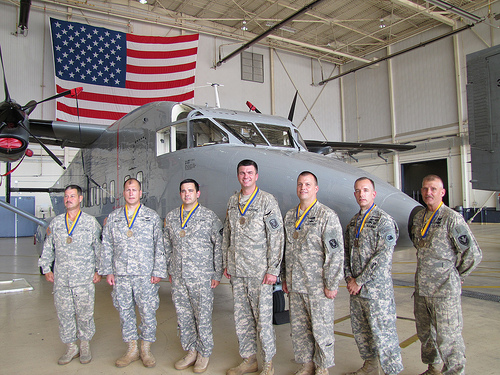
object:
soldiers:
[54, 149, 409, 304]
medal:
[168, 195, 206, 238]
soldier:
[154, 163, 220, 316]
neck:
[174, 201, 210, 218]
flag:
[59, 19, 208, 133]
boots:
[117, 332, 168, 374]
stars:
[62, 3, 114, 64]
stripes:
[115, 52, 246, 145]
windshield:
[221, 125, 297, 147]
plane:
[154, 101, 368, 206]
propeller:
[13, 114, 61, 184]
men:
[45, 158, 478, 341]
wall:
[27, 12, 281, 120]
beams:
[325, 5, 393, 58]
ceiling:
[161, 11, 463, 101]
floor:
[11, 303, 53, 357]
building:
[0, 0, 499, 371]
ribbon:
[117, 198, 135, 213]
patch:
[249, 212, 287, 233]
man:
[209, 129, 306, 335]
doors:
[9, 193, 66, 243]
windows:
[68, 165, 152, 232]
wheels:
[251, 285, 293, 315]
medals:
[42, 206, 447, 228]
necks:
[63, 198, 461, 207]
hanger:
[56, 30, 496, 371]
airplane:
[104, 98, 491, 273]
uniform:
[221, 207, 282, 276]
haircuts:
[54, 172, 221, 195]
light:
[235, 20, 298, 50]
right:
[42, 104, 166, 188]